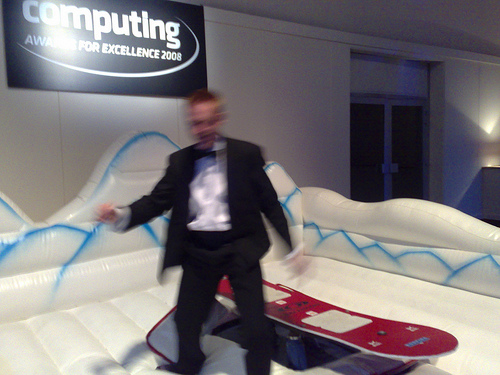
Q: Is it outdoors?
A: Yes, it is outdoors.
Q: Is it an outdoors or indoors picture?
A: It is outdoors.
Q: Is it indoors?
A: No, it is outdoors.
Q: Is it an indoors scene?
A: No, it is outdoors.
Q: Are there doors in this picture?
A: Yes, there is a door.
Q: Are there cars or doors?
A: Yes, there is a door.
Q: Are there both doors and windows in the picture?
A: No, there is a door but no windows.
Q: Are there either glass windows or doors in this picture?
A: Yes, there is a glass door.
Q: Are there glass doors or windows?
A: Yes, there is a glass door.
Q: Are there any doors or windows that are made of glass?
A: Yes, the door is made of glass.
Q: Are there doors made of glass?
A: Yes, there is a door that is made of glass.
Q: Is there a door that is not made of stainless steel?
A: Yes, there is a door that is made of glass.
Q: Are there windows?
A: No, there are no windows.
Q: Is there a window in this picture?
A: No, there are no windows.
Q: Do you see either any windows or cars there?
A: No, there are no windows or cars.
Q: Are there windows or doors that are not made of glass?
A: No, there is a door but it is made of glass.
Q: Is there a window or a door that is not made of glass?
A: No, there is a door but it is made of glass.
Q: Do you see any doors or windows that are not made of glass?
A: No, there is a door but it is made of glass.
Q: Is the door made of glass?
A: Yes, the door is made of glass.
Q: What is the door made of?
A: The door is made of glass.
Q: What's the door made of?
A: The door is made of glass.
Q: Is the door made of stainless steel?
A: No, the door is made of glass.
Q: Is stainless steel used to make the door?
A: No, the door is made of glass.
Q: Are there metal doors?
A: No, there is a door but it is made of glass.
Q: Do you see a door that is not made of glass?
A: No, there is a door but it is made of glass.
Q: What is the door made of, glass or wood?
A: The door is made of glass.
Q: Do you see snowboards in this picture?
A: Yes, there is a snowboard.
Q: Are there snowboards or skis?
A: Yes, there is a snowboard.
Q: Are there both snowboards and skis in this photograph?
A: No, there is a snowboard but no skis.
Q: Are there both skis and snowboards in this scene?
A: No, there is a snowboard but no skis.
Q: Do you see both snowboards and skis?
A: No, there is a snowboard but no skis.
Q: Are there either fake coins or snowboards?
A: Yes, there is a fake snowboard.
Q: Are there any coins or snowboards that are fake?
A: Yes, the snowboard is fake.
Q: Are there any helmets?
A: No, there are no helmets.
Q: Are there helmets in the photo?
A: No, there are no helmets.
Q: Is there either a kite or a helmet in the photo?
A: No, there are no helmets or kites.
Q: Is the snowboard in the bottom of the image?
A: Yes, the snowboard is in the bottom of the image.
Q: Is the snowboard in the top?
A: No, the snowboard is in the bottom of the image.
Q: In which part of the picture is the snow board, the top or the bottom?
A: The snow board is in the bottom of the image.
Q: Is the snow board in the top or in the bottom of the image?
A: The snow board is in the bottom of the image.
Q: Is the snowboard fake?
A: Yes, the snowboard is fake.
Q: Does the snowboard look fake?
A: Yes, the snowboard is fake.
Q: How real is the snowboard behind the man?
A: The snowboard is fake.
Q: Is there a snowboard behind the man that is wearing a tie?
A: Yes, there is a snowboard behind the man.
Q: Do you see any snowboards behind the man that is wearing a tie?
A: Yes, there is a snowboard behind the man.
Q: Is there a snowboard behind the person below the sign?
A: Yes, there is a snowboard behind the man.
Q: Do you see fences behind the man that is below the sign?
A: No, there is a snowboard behind the man.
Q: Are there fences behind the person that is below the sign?
A: No, there is a snowboard behind the man.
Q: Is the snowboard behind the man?
A: Yes, the snowboard is behind the man.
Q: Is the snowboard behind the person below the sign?
A: Yes, the snowboard is behind the man.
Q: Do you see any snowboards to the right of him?
A: Yes, there is a snowboard to the right of the man.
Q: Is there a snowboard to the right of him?
A: Yes, there is a snowboard to the right of the man.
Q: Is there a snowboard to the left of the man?
A: No, the snowboard is to the right of the man.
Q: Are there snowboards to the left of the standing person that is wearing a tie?
A: No, the snowboard is to the right of the man.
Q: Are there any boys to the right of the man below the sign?
A: No, there is a snowboard to the right of the man.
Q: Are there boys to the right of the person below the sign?
A: No, there is a snowboard to the right of the man.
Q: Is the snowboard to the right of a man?
A: Yes, the snowboard is to the right of a man.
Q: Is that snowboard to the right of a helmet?
A: No, the snowboard is to the right of a man.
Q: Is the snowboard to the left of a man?
A: No, the snowboard is to the right of a man.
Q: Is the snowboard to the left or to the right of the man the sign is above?
A: The snowboard is to the right of the man.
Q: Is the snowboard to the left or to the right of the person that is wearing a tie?
A: The snowboard is to the right of the man.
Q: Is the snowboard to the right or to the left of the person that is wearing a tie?
A: The snowboard is to the right of the man.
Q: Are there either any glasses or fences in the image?
A: No, there are no fences or glasses.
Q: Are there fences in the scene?
A: No, there are no fences.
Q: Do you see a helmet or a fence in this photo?
A: No, there are no fences or helmets.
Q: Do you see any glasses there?
A: No, there are no glasses.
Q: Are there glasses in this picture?
A: No, there are no glasses.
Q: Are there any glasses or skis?
A: No, there are no glasses or skis.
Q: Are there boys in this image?
A: No, there are no boys.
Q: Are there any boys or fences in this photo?
A: No, there are no boys or fences.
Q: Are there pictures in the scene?
A: No, there are no pictures.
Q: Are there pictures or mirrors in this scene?
A: No, there are no pictures or mirrors.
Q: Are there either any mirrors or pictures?
A: No, there are no pictures or mirrors.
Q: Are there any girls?
A: No, there are no girls.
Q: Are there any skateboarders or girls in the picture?
A: No, there are no girls or skateboarders.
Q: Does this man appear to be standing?
A: Yes, the man is standing.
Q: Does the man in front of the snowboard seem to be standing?
A: Yes, the man is standing.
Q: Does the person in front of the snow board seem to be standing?
A: Yes, the man is standing.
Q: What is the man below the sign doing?
A: The man is standing.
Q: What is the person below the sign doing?
A: The man is standing.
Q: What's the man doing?
A: The man is standing.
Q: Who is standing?
A: The man is standing.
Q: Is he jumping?
A: No, the man is standing.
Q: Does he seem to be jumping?
A: No, the man is standing.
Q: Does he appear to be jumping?
A: No, the man is standing.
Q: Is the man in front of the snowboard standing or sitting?
A: The man is standing.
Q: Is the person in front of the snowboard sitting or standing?
A: The man is standing.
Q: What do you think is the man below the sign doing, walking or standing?
A: The man is standing.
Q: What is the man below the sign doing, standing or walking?
A: The man is standing.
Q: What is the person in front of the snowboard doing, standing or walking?
A: The man is standing.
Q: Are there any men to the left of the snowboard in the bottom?
A: Yes, there is a man to the left of the snow board.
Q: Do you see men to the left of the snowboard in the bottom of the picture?
A: Yes, there is a man to the left of the snow board.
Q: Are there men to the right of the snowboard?
A: No, the man is to the left of the snowboard.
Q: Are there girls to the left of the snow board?
A: No, there is a man to the left of the snow board.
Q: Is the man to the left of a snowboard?
A: Yes, the man is to the left of a snowboard.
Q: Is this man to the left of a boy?
A: No, the man is to the left of a snowboard.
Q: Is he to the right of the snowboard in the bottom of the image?
A: No, the man is to the left of the snowboard.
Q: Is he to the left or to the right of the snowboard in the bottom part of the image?
A: The man is to the left of the snowboard.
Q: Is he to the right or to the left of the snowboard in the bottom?
A: The man is to the left of the snowboard.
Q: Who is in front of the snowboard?
A: The man is in front of the snowboard.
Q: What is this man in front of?
A: The man is in front of the snowboard.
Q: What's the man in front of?
A: The man is in front of the snowboard.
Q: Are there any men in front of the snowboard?
A: Yes, there is a man in front of the snowboard.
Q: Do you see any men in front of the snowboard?
A: Yes, there is a man in front of the snowboard.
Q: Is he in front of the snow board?
A: Yes, the man is in front of the snow board.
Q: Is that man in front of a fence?
A: No, the man is in front of the snow board.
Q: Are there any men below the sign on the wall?
A: Yes, there is a man below the sign.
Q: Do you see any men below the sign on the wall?
A: Yes, there is a man below the sign.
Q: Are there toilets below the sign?
A: No, there is a man below the sign.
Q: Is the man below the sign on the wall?
A: Yes, the man is below the sign.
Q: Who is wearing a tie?
A: The man is wearing a tie.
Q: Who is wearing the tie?
A: The man is wearing a tie.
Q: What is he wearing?
A: The man is wearing a necktie.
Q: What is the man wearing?
A: The man is wearing a necktie.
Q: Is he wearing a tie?
A: Yes, the man is wearing a tie.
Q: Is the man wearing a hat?
A: No, the man is wearing a tie.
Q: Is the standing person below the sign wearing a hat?
A: No, the man is wearing a tie.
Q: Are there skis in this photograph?
A: No, there are no skis.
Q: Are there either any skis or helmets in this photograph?
A: No, there are no skis or helmets.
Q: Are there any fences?
A: No, there are no fences.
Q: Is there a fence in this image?
A: No, there are no fences.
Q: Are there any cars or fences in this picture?
A: No, there are no fences or cars.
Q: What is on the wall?
A: The sign is on the wall.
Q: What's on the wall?
A: The sign is on the wall.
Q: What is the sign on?
A: The sign is on the wall.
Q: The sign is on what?
A: The sign is on the wall.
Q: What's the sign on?
A: The sign is on the wall.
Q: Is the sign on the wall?
A: Yes, the sign is on the wall.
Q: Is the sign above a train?
A: No, the sign is above the man.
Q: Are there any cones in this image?
A: No, there are no cones.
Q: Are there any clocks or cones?
A: No, there are no cones or clocks.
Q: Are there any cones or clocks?
A: No, there are no cones or clocks.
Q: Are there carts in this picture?
A: No, there are no carts.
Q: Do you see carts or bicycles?
A: No, there are no carts or bicycles.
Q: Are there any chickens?
A: No, there are no chickens.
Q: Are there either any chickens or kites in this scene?
A: No, there are no chickens or kites.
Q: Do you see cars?
A: No, there are no cars.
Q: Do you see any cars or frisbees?
A: No, there are no cars or frisbees.